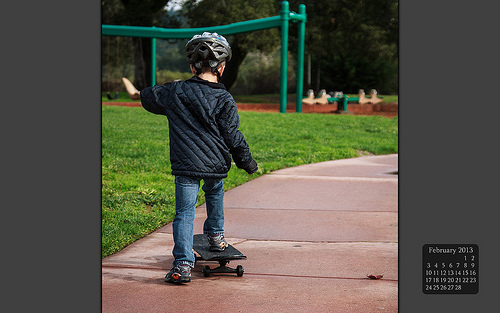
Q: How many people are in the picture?
A: One.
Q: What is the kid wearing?
A: Helmet.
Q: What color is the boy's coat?
A: Navy.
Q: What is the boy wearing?
A: Jeans.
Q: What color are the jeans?
A: Blue.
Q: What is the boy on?
A: Skateboard.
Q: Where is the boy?
A: Park.